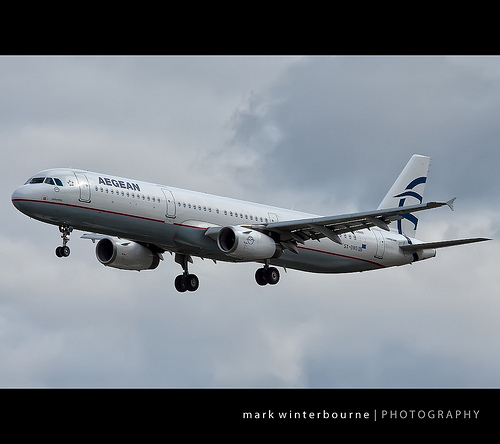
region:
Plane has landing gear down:
[12, 123, 469, 353]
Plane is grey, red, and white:
[12, 126, 432, 319]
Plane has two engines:
[93, 222, 282, 277]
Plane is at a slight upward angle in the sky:
[16, 129, 477, 329]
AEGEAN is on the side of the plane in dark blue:
[62, 155, 152, 198]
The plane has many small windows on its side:
[89, 174, 291, 244]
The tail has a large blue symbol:
[394, 148, 436, 260]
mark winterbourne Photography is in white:
[224, 393, 478, 430]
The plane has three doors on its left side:
[67, 158, 386, 269]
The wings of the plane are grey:
[237, 201, 442, 236]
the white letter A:
[252, 407, 262, 419]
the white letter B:
[321, 405, 331, 420]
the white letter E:
[362, 410, 371, 424]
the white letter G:
[423, 403, 437, 423]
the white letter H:
[461, 407, 473, 422]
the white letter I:
[286, 406, 296, 421]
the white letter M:
[241, 407, 253, 419]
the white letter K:
[268, 407, 276, 418]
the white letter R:
[258, 407, 268, 422]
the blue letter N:
[131, 177, 142, 194]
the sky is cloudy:
[113, 99, 345, 210]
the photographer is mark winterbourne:
[229, 402, 364, 441]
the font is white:
[233, 396, 436, 441]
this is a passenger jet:
[2, 96, 482, 354]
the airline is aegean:
[91, 167, 266, 266]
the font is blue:
[76, 144, 205, 228]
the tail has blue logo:
[310, 159, 490, 304]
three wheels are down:
[14, 156, 491, 339]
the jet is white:
[13, 137, 499, 319]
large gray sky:
[25, 63, 437, 163]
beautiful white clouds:
[0, 73, 277, 140]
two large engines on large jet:
[15, 213, 447, 323]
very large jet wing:
[191, 170, 459, 274]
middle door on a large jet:
[153, 157, 236, 232]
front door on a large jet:
[52, 158, 102, 223]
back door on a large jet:
[351, 217, 406, 269]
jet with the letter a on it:
[32, 170, 204, 218]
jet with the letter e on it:
[77, 163, 156, 211]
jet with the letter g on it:
[77, 168, 182, 201]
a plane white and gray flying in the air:
[7, 147, 495, 297]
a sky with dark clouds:
[0, 59, 498, 387]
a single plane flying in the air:
[7, 153, 490, 298]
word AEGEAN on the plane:
[90, 168, 154, 201]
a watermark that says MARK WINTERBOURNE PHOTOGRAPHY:
[223, 381, 488, 431]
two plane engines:
[60, 220, 310, 288]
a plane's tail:
[361, 145, 442, 238]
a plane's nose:
[0, 156, 105, 268]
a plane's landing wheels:
[166, 260, 301, 300]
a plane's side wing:
[234, 188, 467, 245]